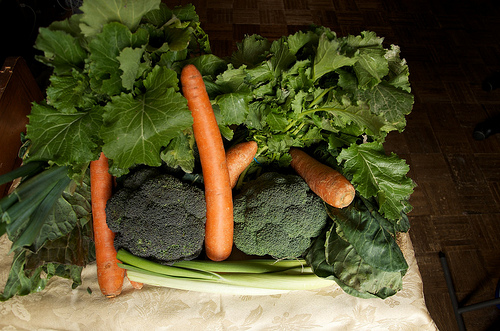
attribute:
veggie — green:
[93, 165, 210, 265]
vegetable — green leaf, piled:
[18, 0, 418, 220]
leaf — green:
[0, 247, 82, 300]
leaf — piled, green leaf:
[336, 42, 413, 132]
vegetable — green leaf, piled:
[56, 50, 420, 282]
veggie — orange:
[194, 107, 303, 232]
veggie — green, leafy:
[67, 8, 172, 135]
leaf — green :
[236, 30, 414, 148]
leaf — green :
[17, 2, 194, 166]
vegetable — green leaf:
[237, 45, 407, 142]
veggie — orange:
[177, 64, 235, 264]